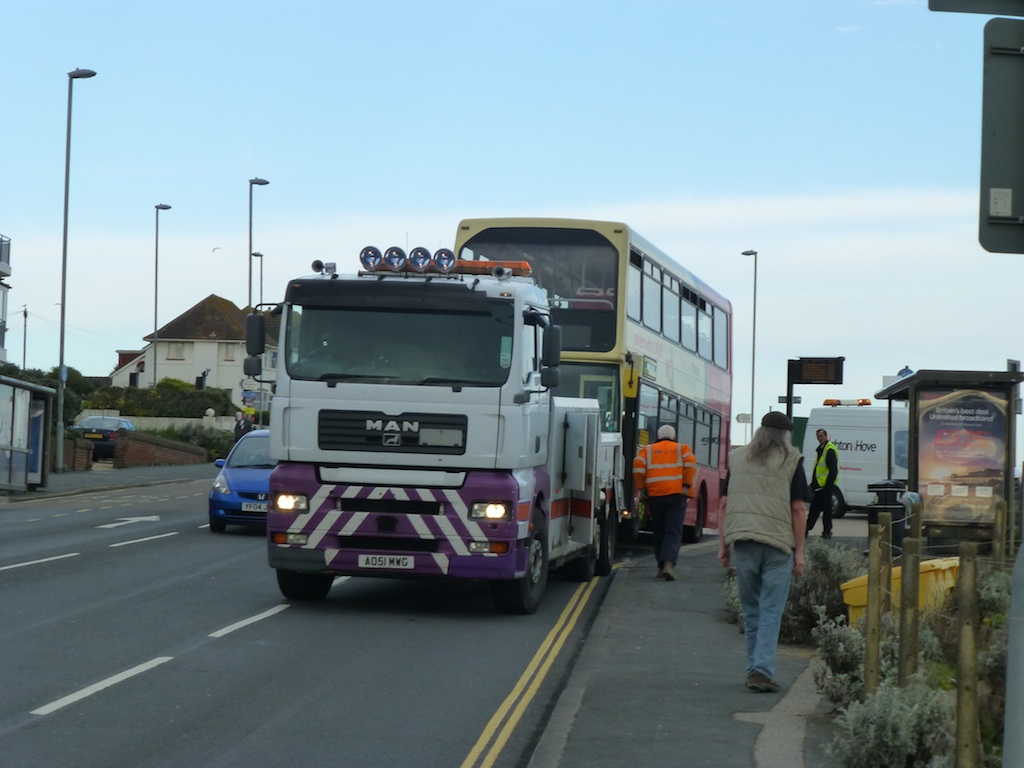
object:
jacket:
[633, 441, 694, 498]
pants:
[647, 493, 686, 571]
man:
[715, 411, 808, 691]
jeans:
[733, 545, 794, 686]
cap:
[759, 411, 794, 433]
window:
[228, 437, 280, 467]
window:
[287, 292, 515, 385]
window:
[458, 240, 617, 307]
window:
[542, 308, 619, 351]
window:
[548, 362, 619, 448]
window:
[624, 263, 640, 323]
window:
[641, 271, 661, 332]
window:
[660, 282, 684, 343]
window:
[679, 297, 699, 355]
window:
[695, 307, 715, 364]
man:
[633, 422, 696, 579]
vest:
[811, 441, 839, 487]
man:
[805, 427, 841, 543]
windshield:
[225, 436, 279, 469]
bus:
[454, 219, 733, 539]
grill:
[317, 407, 469, 457]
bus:
[239, 248, 628, 616]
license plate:
[241, 498, 275, 513]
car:
[208, 422, 277, 527]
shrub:
[838, 684, 953, 766]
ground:
[530, 506, 1023, 766]